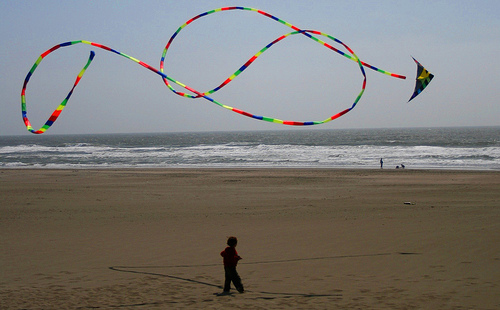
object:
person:
[395, 166, 399, 169]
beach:
[0, 166, 495, 308]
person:
[380, 158, 383, 166]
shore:
[0, 165, 485, 169]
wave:
[3, 147, 500, 160]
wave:
[2, 161, 108, 167]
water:
[1, 127, 500, 168]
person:
[401, 164, 405, 168]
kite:
[17, 5, 433, 134]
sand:
[0, 167, 499, 310]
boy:
[221, 237, 244, 292]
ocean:
[0, 126, 499, 169]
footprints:
[203, 299, 214, 302]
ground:
[0, 168, 499, 309]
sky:
[0, 0, 499, 139]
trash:
[404, 202, 410, 204]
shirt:
[220, 247, 242, 266]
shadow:
[107, 236, 420, 296]